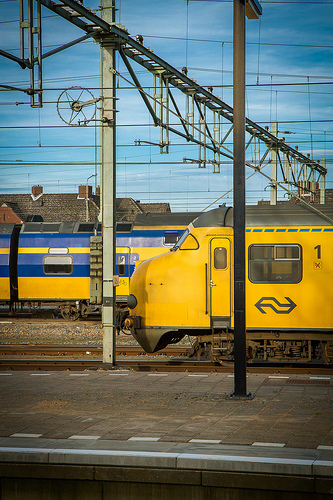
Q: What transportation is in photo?
A: Trains.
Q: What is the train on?
A: Tracks.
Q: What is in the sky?
A: Clouds.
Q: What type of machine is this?
A: A train.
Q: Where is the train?
A: On the tracks.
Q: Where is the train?
A: At a station.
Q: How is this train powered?
A: With electricity.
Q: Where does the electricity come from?
A: From the power lines above.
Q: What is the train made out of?
A: Steel.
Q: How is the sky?
A: Cloudy.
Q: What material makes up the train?
A: Metal.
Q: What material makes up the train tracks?
A: Metal.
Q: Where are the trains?
A: Tracks.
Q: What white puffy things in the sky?
A: Clouds.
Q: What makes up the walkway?
A: Stone.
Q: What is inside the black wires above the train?
A: Electricity.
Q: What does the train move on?
A: Train tracks.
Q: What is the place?
A: Railways.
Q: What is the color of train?
A: Yellow and blue.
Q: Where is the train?
A: On track.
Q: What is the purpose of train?
A: Transportation.